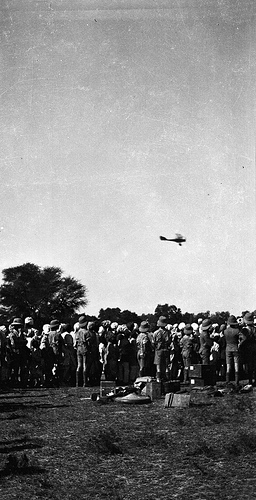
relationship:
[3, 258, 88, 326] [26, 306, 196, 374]
tree above people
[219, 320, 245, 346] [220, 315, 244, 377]
camera on person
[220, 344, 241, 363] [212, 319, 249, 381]
pants on person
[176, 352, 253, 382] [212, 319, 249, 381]
boots on person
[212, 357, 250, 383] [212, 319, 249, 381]
socks on person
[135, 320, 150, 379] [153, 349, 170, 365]
person with shorts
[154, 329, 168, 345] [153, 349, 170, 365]
suspenders on shorts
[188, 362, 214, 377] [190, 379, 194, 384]
box with white label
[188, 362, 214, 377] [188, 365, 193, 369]
box with white label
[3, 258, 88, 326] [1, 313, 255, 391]
tree over heads of spectators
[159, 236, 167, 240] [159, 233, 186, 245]
tail of plane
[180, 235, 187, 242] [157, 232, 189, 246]
nose of plane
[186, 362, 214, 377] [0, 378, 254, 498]
box on ground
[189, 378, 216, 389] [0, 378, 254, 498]
box on ground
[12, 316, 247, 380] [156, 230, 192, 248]
crowd watching airplane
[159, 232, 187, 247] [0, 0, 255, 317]
airplane in sky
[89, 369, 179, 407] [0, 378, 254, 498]
boxes on ground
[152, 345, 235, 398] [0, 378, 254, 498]
bags on ground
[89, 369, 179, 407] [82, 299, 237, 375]
boxes behind crowd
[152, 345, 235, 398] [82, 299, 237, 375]
bags behind crowd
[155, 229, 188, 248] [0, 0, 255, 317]
airplane in sky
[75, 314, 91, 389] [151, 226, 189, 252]
person watching airplane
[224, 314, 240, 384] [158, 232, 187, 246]
person watching airplane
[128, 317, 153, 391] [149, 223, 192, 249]
person watching plane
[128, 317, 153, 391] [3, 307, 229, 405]
person in crowd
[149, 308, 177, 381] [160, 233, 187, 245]
person watching airplane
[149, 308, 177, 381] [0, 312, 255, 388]
person in crowd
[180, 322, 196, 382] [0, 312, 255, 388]
person in crowd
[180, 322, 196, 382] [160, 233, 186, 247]
person watching airplane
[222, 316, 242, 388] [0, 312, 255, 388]
person in crowd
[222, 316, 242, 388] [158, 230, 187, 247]
person watching airplane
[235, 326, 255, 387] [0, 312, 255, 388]
person in crowd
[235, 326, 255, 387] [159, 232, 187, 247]
person watching airplane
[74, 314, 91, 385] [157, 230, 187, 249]
person watching airplane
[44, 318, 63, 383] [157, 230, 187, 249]
person watching airplane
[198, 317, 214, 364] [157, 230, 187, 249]
person watching airplane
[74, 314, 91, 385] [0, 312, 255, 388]
person in crowd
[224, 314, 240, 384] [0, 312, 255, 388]
person in crowd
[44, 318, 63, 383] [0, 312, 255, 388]
person in crowd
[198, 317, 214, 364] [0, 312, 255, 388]
person in crowd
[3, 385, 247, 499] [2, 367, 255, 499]
grass on field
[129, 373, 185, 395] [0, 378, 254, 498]
boxes on ground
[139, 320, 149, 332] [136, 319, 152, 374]
hat on person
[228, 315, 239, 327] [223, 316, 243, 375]
hat on person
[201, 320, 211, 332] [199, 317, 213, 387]
hat on person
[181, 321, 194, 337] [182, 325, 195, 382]
hat on person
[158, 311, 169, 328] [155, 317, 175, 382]
hat on person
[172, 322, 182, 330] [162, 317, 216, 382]
hat on person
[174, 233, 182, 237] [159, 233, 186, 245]
wing on plane